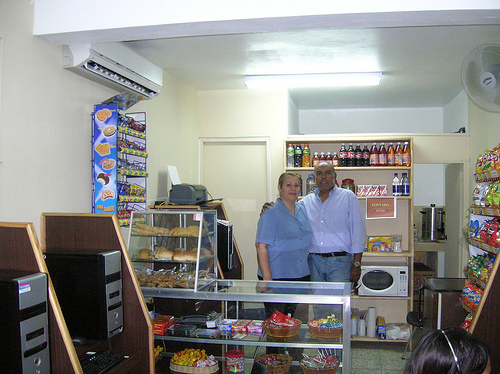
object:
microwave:
[356, 261, 408, 297]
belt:
[309, 251, 348, 257]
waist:
[309, 240, 353, 254]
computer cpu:
[40, 246, 125, 339]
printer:
[166, 163, 224, 205]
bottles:
[286, 143, 295, 168]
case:
[125, 207, 219, 293]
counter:
[135, 276, 352, 305]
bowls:
[383, 326, 400, 338]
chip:
[464, 217, 479, 237]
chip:
[470, 184, 482, 207]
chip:
[474, 153, 484, 178]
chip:
[460, 280, 471, 299]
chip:
[477, 259, 489, 286]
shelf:
[460, 298, 474, 315]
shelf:
[470, 204, 498, 216]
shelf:
[473, 168, 498, 184]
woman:
[257, 171, 316, 355]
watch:
[351, 261, 363, 268]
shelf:
[118, 195, 146, 203]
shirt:
[255, 198, 312, 280]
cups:
[356, 318, 367, 336]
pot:
[418, 202, 445, 241]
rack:
[90, 104, 146, 226]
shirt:
[294, 184, 367, 254]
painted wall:
[0, 0, 198, 247]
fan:
[460, 43, 500, 114]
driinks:
[402, 140, 411, 166]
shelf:
[466, 236, 499, 254]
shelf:
[153, 318, 345, 348]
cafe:
[2, 0, 497, 372]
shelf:
[284, 165, 410, 170]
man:
[259, 161, 366, 364]